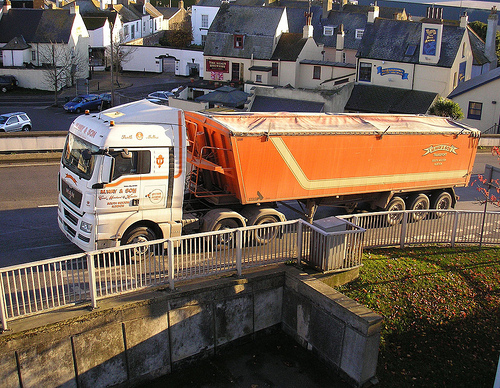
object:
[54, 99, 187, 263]
cab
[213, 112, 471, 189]
bed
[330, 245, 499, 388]
grass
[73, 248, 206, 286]
gate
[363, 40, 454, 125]
business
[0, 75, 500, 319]
road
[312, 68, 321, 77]
window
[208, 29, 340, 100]
building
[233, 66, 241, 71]
window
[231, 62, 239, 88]
door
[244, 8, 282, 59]
roof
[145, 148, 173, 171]
design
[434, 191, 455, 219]
wheel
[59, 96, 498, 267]
truck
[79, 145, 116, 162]
mirror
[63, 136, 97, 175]
window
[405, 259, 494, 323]
ground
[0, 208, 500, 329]
fence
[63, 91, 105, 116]
car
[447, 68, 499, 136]
house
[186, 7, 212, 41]
building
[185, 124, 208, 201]
ladder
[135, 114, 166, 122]
white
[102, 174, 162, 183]
stripe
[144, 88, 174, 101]
car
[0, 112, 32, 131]
suv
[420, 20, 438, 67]
sign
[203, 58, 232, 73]
sign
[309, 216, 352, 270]
can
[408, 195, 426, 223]
wheel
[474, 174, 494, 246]
tree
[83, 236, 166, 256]
rail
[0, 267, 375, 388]
wall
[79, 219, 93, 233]
headlight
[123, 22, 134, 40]
window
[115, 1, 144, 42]
building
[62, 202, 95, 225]
grill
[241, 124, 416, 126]
haul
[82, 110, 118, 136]
lights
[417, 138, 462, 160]
logo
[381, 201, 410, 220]
tire